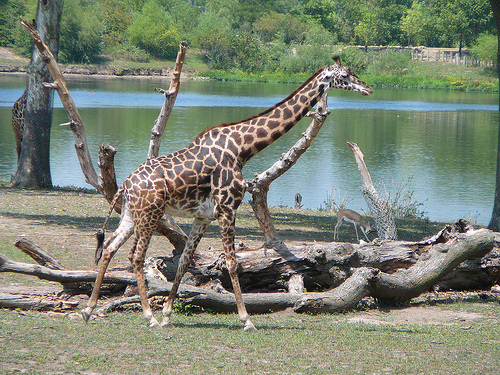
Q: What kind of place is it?
A: It is a lake.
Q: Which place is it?
A: It is a lake.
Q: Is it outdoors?
A: Yes, it is outdoors.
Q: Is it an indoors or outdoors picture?
A: It is outdoors.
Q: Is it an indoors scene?
A: No, it is outdoors.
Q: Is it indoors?
A: No, it is outdoors.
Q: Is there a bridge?
A: Yes, there is a bridge.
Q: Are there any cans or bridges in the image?
A: Yes, there is a bridge.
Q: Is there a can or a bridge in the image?
A: Yes, there is a bridge.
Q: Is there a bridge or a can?
A: Yes, there is a bridge.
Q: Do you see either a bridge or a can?
A: Yes, there is a bridge.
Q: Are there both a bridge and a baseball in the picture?
A: No, there is a bridge but no baseballs.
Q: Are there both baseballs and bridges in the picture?
A: No, there is a bridge but no baseballs.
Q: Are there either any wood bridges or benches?
A: Yes, there is a wood bridge.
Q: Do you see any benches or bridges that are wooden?
A: Yes, the bridge is wooden.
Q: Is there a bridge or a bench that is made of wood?
A: Yes, the bridge is made of wood.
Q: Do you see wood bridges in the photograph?
A: Yes, there is a wood bridge.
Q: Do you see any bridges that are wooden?
A: Yes, there is a bridge that is wooden.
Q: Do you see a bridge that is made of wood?
A: Yes, there is a bridge that is made of wood.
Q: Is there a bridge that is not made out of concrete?
A: Yes, there is a bridge that is made of wood.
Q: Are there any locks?
A: No, there are no locks.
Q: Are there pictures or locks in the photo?
A: No, there are no locks or pictures.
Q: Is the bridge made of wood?
A: Yes, the bridge is made of wood.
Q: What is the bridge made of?
A: The bridge is made of wood.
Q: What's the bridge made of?
A: The bridge is made of wood.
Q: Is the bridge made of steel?
A: No, the bridge is made of wood.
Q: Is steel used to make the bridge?
A: No, the bridge is made of wood.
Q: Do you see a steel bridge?
A: No, there is a bridge but it is made of wood.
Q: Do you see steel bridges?
A: No, there is a bridge but it is made of wood.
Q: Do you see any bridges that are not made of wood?
A: No, there is a bridge but it is made of wood.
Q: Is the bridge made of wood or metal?
A: The bridge is made of wood.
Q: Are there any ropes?
A: No, there are no ropes.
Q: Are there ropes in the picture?
A: No, there are no ropes.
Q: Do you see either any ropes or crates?
A: No, there are no ropes or crates.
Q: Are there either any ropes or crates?
A: No, there are no ropes or crates.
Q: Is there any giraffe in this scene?
A: Yes, there is a giraffe.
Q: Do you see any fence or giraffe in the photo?
A: Yes, there is a giraffe.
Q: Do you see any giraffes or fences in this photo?
A: Yes, there is a giraffe.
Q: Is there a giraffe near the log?
A: Yes, there is a giraffe near the log.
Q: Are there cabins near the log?
A: No, there is a giraffe near the log.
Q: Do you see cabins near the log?
A: No, there is a giraffe near the log.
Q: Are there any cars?
A: No, there are no cars.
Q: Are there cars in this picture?
A: No, there are no cars.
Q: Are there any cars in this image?
A: No, there are no cars.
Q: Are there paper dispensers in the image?
A: No, there are no paper dispensers.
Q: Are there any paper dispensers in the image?
A: No, there are no paper dispensers.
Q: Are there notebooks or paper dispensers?
A: No, there are no paper dispensers or notebooks.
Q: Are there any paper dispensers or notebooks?
A: No, there are no paper dispensers or notebooks.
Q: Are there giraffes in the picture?
A: Yes, there is a giraffe.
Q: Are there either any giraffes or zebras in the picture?
A: Yes, there is a giraffe.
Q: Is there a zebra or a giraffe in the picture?
A: Yes, there is a giraffe.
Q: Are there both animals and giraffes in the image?
A: Yes, there are both a giraffe and animals.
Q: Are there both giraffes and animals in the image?
A: Yes, there are both a giraffe and animals.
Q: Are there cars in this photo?
A: No, there are no cars.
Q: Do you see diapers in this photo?
A: No, there are no diapers.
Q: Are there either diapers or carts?
A: No, there are no diapers or carts.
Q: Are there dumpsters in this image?
A: No, there are no dumpsters.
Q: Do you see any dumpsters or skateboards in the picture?
A: No, there are no dumpsters or skateboards.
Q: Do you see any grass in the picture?
A: Yes, there is grass.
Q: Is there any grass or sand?
A: Yes, there is grass.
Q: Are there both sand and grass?
A: No, there is grass but no sand.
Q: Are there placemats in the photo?
A: No, there are no placemats.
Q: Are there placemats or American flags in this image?
A: No, there are no placemats or American flags.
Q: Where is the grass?
A: The grass is on the ground.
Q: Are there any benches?
A: No, there are no benches.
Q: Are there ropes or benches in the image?
A: No, there are no benches or ropes.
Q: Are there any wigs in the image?
A: No, there are no wigs.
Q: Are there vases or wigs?
A: No, there are no wigs or vases.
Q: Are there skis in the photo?
A: No, there are no skis.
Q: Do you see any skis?
A: No, there are no skis.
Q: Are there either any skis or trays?
A: No, there are no skis or trays.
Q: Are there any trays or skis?
A: No, there are no skis or trays.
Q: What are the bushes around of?
A: The bushes are around the lake.